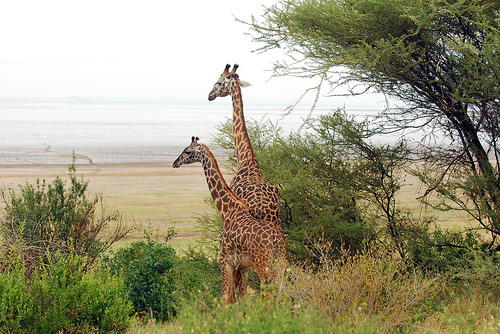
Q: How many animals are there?
A: Two.